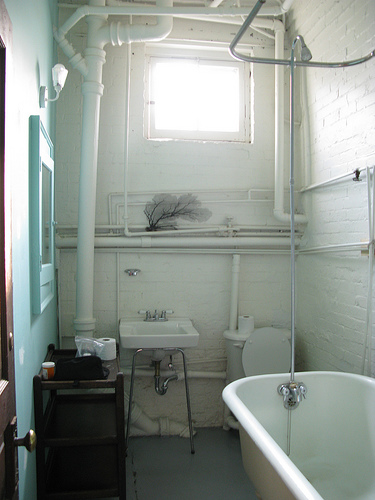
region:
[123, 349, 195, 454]
Metal legs under a sink.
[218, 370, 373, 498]
A white bathtub.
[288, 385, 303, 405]
Silver faucet in the bathtub.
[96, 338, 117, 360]
A white roll of toilet paper on a wood stand.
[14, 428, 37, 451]
A gold knob on a brown door.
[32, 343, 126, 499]
A dark wood shelf against the wall.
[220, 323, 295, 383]
A white toilet with lid up.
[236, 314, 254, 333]
White roll of toilet paper on the back of the toilet tank.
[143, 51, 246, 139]
Square window in the bathroom.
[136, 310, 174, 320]
Right and left knobs on a sink.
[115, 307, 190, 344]
white sink in bathroom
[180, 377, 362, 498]
white tub in bathroom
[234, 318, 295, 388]
white lid on toilet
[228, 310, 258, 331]
white toilet roll on tank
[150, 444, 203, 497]
floor is light grey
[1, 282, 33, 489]
brown door in bathroom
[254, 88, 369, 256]
white pipes on wall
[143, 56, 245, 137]
white frame on window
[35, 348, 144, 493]
black shelf near sink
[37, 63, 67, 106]
light fixture on the wall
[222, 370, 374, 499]
part of a large white bathtub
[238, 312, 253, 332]
roll of toilet paper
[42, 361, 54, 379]
large prescription pill bottle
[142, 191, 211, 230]
dark bonsai style tree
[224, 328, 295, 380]
top part of a toilet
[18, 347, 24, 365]
white light switch plate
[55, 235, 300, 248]
large white pipe on the back wall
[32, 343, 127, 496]
two shelf system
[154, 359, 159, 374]
visible copper wire under the sink